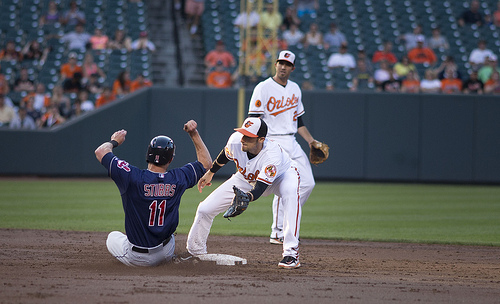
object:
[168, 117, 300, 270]
man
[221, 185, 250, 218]
glove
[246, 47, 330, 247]
man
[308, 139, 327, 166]
glove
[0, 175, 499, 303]
field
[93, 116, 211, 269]
man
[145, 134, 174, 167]
helmet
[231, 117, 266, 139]
hat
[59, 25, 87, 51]
spectators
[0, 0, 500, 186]
stands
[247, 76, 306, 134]
jersey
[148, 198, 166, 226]
11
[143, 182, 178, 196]
name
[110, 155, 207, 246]
jersey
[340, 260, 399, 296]
tracks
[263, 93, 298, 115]
lettering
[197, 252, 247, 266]
base